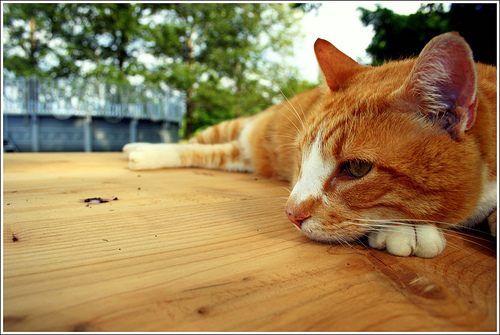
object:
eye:
[336, 157, 374, 178]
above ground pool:
[4, 77, 181, 152]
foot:
[367, 220, 447, 259]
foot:
[118, 141, 180, 172]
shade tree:
[7, 6, 66, 77]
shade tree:
[177, 5, 318, 141]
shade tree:
[353, 1, 499, 71]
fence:
[4, 78, 189, 122]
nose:
[286, 210, 311, 227]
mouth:
[316, 220, 378, 245]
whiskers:
[345, 219, 491, 230]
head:
[287, 60, 487, 241]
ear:
[312, 37, 360, 94]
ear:
[393, 30, 477, 136]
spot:
[294, 135, 338, 199]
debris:
[83, 195, 102, 205]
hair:
[326, 55, 449, 122]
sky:
[6, 3, 475, 119]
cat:
[122, 31, 500, 259]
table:
[139, 294, 498, 333]